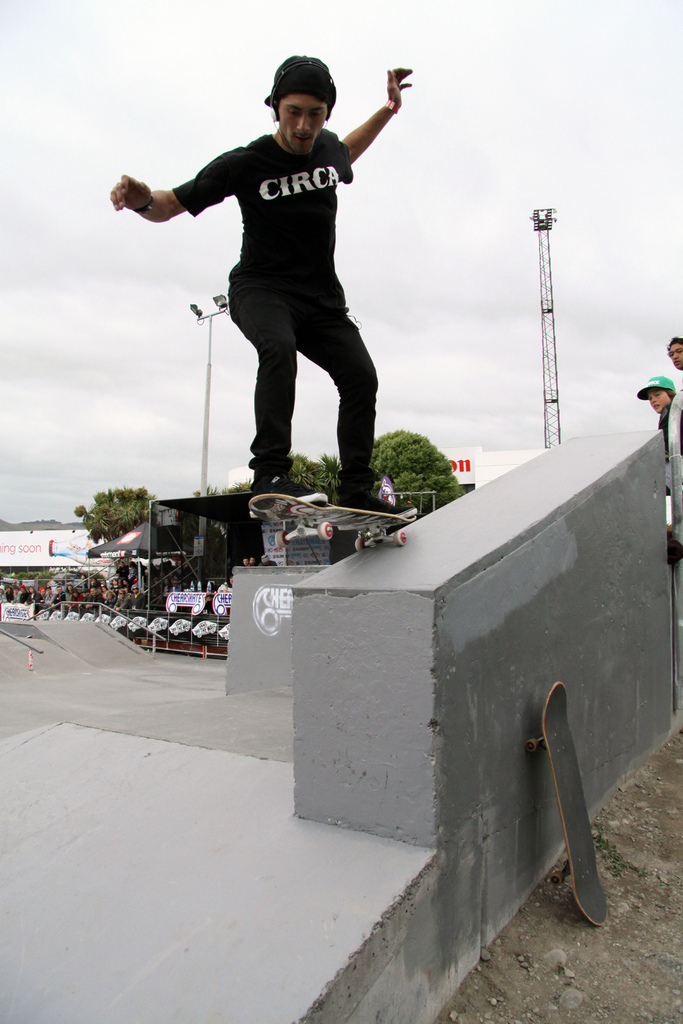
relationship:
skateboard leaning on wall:
[518, 676, 637, 935] [304, 419, 674, 1021]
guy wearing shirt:
[108, 54, 411, 523] [165, 126, 369, 317]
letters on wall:
[252, 574, 294, 642] [222, 579, 296, 687]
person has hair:
[642, 340, 659, 374] [640, 341, 661, 365]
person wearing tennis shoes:
[109, 43, 424, 519] [243, 456, 425, 519]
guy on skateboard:
[103, 49, 429, 522] [243, 490, 415, 548]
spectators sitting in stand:
[94, 579, 132, 612] [2, 556, 174, 630]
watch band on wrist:
[137, 187, 153, 223] [125, 187, 162, 226]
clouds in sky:
[22, 36, 183, 181] [15, 9, 645, 282]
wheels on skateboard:
[264, 510, 413, 554] [244, 493, 417, 557]